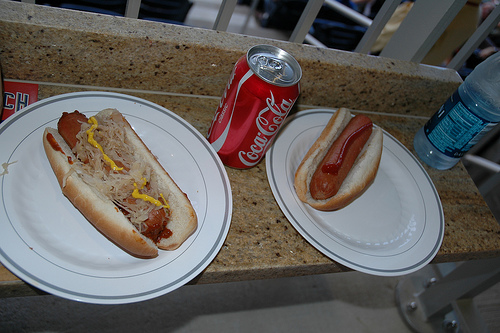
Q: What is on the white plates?
A: Hot dogs.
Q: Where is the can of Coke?
A: Between the two plates.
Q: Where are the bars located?
A: Behind the shelf.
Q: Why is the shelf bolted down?
A: Stability and safety reasons.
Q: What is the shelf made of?
A: Marble.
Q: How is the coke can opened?
A: With the pop tab?.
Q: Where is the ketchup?
A: The hot dog on the right.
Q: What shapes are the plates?
A: Round.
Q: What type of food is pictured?
A: Hot dogs and soda.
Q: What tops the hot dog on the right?
A: Ketchup.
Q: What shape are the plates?
A: Round.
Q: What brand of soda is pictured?
A: Coca-Cola.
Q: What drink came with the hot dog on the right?
A: Bottled water.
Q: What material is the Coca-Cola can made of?
A: Aluminum.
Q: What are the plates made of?
A: Glass.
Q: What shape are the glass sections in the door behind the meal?
A: Rectangle.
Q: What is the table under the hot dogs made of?
A: Granite.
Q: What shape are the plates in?
A: Round.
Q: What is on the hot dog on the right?
A: Ketchup.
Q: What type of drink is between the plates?
A: Soda.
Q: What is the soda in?
A: Can.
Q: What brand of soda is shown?
A: Coca-cola.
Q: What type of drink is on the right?
A: Water.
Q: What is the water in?
A: Plastic bottle.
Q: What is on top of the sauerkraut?
A: Mustard.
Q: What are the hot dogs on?
A: Buns.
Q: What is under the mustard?
A: Sauerkraut.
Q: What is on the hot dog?
A: Yellow mustard.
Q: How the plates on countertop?
A: Side by side.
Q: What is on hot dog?
A: Sauerkraut.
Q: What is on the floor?
A: Shadow.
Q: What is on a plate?
A: Hot dog.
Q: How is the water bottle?
A: Clear.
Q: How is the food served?
A: On white plates.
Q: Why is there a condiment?
A: Flavor.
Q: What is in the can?
A: Coke.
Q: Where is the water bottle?
A: Right side.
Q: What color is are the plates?
A: White.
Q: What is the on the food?
A: Sauces.